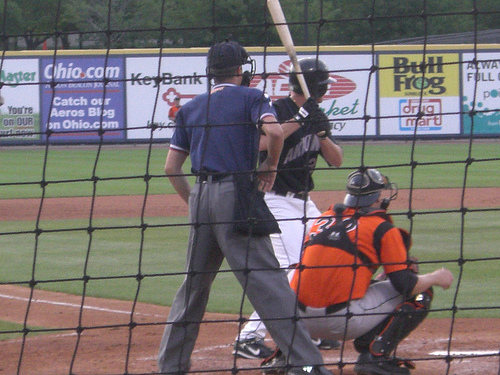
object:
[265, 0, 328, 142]
bat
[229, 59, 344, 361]
player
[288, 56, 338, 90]
helmet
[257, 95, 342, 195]
jersey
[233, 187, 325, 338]
pants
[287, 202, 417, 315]
jersey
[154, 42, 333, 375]
men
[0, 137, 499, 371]
baseball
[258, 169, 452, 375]
catcher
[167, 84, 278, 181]
shirt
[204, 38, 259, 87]
hat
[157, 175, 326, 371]
pants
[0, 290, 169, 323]
line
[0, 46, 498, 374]
field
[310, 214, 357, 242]
number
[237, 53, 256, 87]
mask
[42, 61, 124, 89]
sponsor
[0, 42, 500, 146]
wall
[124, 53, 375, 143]
poster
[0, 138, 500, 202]
grass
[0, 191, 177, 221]
dirt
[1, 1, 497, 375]
net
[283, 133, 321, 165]
word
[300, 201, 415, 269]
strap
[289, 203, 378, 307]
back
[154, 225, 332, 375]
legs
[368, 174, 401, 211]
mask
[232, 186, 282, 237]
bag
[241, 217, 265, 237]
baseballs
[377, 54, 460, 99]
advertising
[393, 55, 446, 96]
bull frog